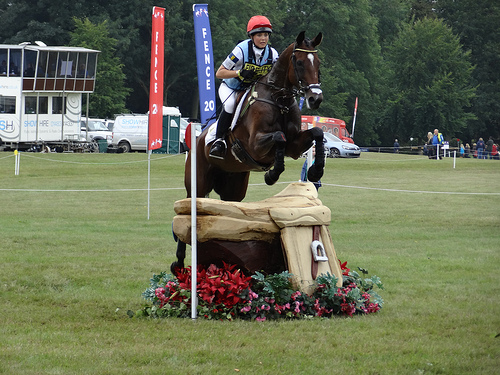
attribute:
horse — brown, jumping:
[169, 32, 326, 285]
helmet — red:
[246, 14, 274, 35]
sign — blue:
[191, 2, 217, 130]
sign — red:
[150, 5, 163, 155]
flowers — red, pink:
[139, 260, 383, 317]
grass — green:
[1, 151, 499, 374]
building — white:
[1, 42, 100, 150]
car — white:
[319, 129, 360, 160]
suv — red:
[301, 114, 355, 144]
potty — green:
[152, 106, 181, 153]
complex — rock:
[175, 181, 347, 294]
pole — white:
[186, 121, 198, 320]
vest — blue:
[223, 40, 271, 90]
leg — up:
[292, 124, 325, 187]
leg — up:
[247, 104, 285, 185]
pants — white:
[217, 81, 241, 118]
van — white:
[111, 114, 192, 152]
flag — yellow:
[13, 149, 19, 155]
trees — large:
[1, 0, 499, 154]